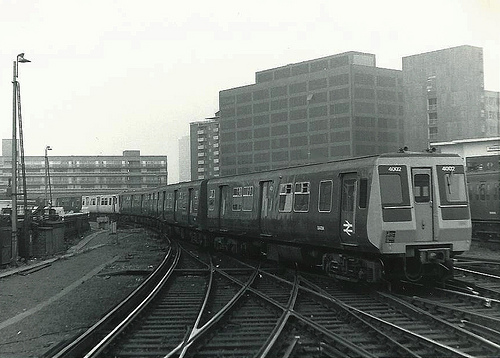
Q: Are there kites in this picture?
A: No, there are no kites.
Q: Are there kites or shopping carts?
A: No, there are no kites or shopping carts.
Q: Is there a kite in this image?
A: No, there are no kites.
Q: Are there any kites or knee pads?
A: No, there are no kites or knee pads.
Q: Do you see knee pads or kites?
A: No, there are no kites or knee pads.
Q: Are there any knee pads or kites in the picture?
A: No, there are no kites or knee pads.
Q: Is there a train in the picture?
A: Yes, there is a train.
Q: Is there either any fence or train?
A: Yes, there is a train.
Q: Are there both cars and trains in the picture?
A: Yes, there are both a train and a car.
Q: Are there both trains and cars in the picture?
A: Yes, there are both a train and a car.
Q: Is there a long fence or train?
A: Yes, there is a long train.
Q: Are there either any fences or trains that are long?
A: Yes, the train is long.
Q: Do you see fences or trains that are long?
A: Yes, the train is long.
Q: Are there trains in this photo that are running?
A: Yes, there is a train that is running.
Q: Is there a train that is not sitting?
A: Yes, there is a train that is running.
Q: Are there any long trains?
A: Yes, there is a long train.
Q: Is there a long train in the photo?
A: Yes, there is a long train.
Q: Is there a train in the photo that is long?
A: Yes, there is a train that is long.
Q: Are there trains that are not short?
A: Yes, there is a long train.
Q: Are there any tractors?
A: No, there are no tractors.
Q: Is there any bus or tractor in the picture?
A: No, there are no tractors or buses.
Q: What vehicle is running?
A: The vehicle is a train.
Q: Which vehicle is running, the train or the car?
A: The train is running.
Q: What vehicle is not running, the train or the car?
A: The car is not running.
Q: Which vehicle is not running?
A: The vehicle is a car.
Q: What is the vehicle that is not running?
A: The vehicle is a car.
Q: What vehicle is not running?
A: The vehicle is a car.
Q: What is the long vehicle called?
A: The vehicle is a train.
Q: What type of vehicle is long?
A: The vehicle is a train.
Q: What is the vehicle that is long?
A: The vehicle is a train.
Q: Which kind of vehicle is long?
A: The vehicle is a train.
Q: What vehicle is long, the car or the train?
A: The train is long.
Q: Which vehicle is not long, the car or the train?
A: The car is not long.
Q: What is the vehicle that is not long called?
A: The vehicle is a car.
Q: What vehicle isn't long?
A: The vehicle is a car.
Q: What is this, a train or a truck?
A: This is a train.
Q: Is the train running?
A: Yes, the train is running.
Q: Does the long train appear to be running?
A: Yes, the train is running.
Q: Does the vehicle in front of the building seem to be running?
A: Yes, the train is running.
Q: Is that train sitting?
A: No, the train is running.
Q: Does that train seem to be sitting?
A: No, the train is running.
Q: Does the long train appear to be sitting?
A: No, the train is running.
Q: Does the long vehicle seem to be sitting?
A: No, the train is running.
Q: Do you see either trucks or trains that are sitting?
A: No, there is a train but it is running.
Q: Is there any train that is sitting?
A: No, there is a train but it is running.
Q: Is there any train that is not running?
A: No, there is a train but it is running.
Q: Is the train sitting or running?
A: The train is running.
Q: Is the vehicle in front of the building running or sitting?
A: The train is running.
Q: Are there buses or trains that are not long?
A: No, there is a train but it is long.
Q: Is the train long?
A: Yes, the train is long.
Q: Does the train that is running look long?
A: Yes, the train is long.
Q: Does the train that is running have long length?
A: Yes, the train is long.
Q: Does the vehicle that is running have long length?
A: Yes, the train is long.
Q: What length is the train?
A: The train is long.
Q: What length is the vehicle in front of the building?
A: The train is long.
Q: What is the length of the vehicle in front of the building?
A: The train is long.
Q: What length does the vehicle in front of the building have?
A: The train has long length.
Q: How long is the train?
A: The train is long.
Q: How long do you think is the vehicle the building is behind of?
A: The train is long.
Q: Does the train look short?
A: No, the train is long.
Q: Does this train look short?
A: No, the train is long.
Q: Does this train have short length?
A: No, the train is long.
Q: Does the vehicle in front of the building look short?
A: No, the train is long.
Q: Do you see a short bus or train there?
A: No, there is a train but it is long.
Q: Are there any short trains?
A: No, there is a train but it is long.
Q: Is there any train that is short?
A: No, there is a train but it is long.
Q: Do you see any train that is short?
A: No, there is a train but it is long.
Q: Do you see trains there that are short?
A: No, there is a train but it is long.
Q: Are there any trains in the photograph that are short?
A: No, there is a train but it is long.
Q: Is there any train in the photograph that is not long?
A: No, there is a train but it is long.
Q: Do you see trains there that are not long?
A: No, there is a train but it is long.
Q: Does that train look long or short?
A: The train is long.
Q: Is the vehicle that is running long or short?
A: The train is long.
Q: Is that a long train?
A: Yes, that is a long train.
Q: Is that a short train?
A: No, that is a long train.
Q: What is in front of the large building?
A: The train is in front of the building.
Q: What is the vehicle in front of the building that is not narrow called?
A: The vehicle is a train.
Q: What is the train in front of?
A: The train is in front of the building.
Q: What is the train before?
A: The train is in front of the building.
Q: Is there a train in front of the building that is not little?
A: Yes, there is a train in front of the building.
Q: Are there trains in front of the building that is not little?
A: Yes, there is a train in front of the building.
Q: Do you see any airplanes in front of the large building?
A: No, there is a train in front of the building.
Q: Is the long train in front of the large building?
A: Yes, the train is in front of the building.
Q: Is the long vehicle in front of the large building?
A: Yes, the train is in front of the building.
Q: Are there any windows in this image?
A: Yes, there is a window.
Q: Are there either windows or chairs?
A: Yes, there is a window.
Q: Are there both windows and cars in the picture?
A: Yes, there are both a window and a car.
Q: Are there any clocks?
A: No, there are no clocks.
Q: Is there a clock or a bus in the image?
A: No, there are no clocks or buses.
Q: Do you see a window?
A: Yes, there is a window.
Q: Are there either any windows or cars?
A: Yes, there is a window.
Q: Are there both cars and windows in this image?
A: Yes, there are both a window and a car.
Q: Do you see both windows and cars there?
A: Yes, there are both a window and a car.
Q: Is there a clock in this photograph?
A: No, there are no clocks.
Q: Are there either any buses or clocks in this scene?
A: No, there are no clocks or buses.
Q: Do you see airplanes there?
A: No, there are no airplanes.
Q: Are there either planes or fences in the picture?
A: No, there are no planes or fences.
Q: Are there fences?
A: No, there are no fences.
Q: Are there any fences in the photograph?
A: No, there are no fences.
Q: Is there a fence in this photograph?
A: No, there are no fences.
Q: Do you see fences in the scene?
A: No, there are no fences.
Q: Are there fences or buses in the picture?
A: No, there are no fences or buses.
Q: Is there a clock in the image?
A: No, there are no clocks.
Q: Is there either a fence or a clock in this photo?
A: No, there are no clocks or fences.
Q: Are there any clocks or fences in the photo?
A: No, there are no clocks or fences.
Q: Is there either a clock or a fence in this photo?
A: No, there are no clocks or fences.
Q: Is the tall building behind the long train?
A: Yes, the building is behind the train.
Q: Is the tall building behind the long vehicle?
A: Yes, the building is behind the train.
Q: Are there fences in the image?
A: No, there are no fences.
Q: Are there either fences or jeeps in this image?
A: No, there are no fences or jeeps.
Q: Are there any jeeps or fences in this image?
A: No, there are no fences or jeeps.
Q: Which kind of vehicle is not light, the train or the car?
A: The train is not light.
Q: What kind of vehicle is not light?
A: The vehicle is a train.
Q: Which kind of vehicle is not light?
A: The vehicle is a train.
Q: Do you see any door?
A: Yes, there is a door.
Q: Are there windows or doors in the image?
A: Yes, there is a door.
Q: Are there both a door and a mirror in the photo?
A: No, there is a door but no mirrors.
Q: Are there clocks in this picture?
A: No, there are no clocks.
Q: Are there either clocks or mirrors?
A: No, there are no clocks or mirrors.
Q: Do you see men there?
A: No, there are no men.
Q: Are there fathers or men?
A: No, there are no men or fathers.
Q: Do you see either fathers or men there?
A: No, there are no men or fathers.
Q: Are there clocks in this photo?
A: No, there are no clocks.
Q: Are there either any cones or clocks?
A: No, there are no clocks or cones.